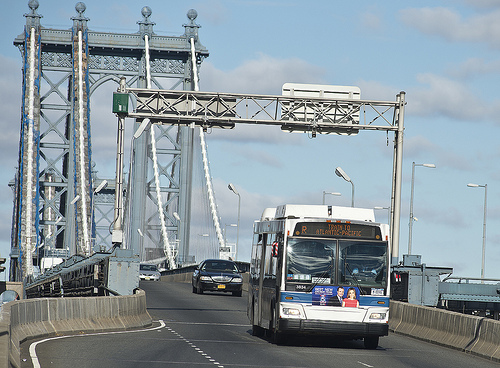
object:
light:
[466, 183, 479, 188]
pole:
[479, 184, 488, 284]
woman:
[341, 288, 358, 308]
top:
[343, 298, 359, 308]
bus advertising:
[312, 285, 360, 307]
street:
[131, 289, 240, 348]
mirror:
[271, 241, 280, 257]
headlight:
[283, 307, 301, 315]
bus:
[246, 204, 403, 349]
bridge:
[0, 1, 500, 368]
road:
[0, 279, 500, 364]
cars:
[139, 263, 161, 282]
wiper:
[307, 262, 365, 294]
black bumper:
[279, 318, 389, 337]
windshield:
[202, 260, 238, 270]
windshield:
[140, 265, 157, 271]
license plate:
[217, 284, 225, 289]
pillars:
[228, 182, 242, 260]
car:
[192, 259, 245, 297]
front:
[285, 238, 389, 296]